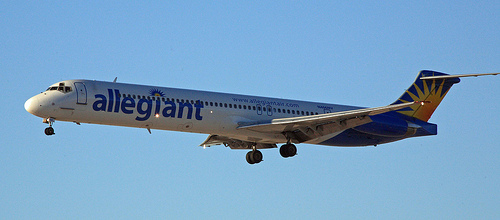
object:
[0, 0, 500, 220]
sky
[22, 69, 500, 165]
airplane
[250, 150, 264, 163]
wheel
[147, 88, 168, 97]
logo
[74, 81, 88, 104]
door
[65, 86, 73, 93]
window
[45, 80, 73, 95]
cockpit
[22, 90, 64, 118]
nose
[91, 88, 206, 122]
print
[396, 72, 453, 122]
lego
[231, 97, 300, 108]
address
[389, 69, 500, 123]
tail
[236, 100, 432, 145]
wing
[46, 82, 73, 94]
windshield